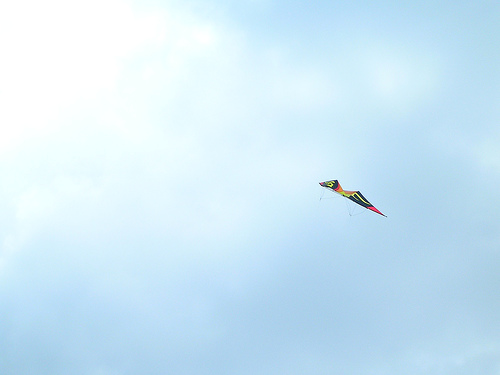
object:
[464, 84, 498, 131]
sky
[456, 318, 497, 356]
sky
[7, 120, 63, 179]
clouds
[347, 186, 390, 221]
wing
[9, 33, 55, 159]
air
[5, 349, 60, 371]
sky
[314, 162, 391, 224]
kite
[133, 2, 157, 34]
clouds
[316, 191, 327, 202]
string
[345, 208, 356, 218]
string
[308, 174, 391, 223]
glider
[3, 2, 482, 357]
weather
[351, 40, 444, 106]
cloud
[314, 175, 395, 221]
plane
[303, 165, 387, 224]
kite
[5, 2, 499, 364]
day picture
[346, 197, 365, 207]
white lines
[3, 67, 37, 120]
clouds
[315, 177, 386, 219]
kite thread